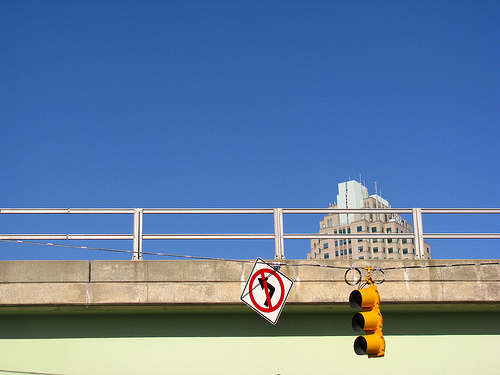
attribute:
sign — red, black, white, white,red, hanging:
[240, 256, 294, 325]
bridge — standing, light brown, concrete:
[0, 207, 499, 373]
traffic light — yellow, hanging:
[349, 267, 386, 358]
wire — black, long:
[1, 237, 500, 270]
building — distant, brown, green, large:
[307, 173, 432, 260]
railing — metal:
[0, 207, 499, 259]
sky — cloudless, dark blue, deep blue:
[1, 0, 499, 261]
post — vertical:
[132, 210, 143, 262]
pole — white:
[374, 179, 378, 195]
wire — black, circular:
[344, 267, 362, 285]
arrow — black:
[258, 277, 275, 306]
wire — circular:
[370, 269, 386, 285]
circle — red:
[248, 269, 286, 314]